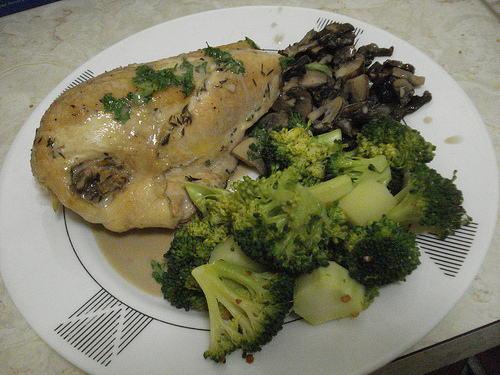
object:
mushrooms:
[267, 21, 437, 146]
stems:
[294, 263, 366, 323]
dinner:
[31, 17, 469, 361]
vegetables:
[281, 120, 332, 173]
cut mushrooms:
[320, 23, 355, 53]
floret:
[345, 219, 419, 283]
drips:
[444, 133, 462, 148]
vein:
[37, 4, 76, 50]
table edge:
[381, 324, 497, 375]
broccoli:
[229, 175, 351, 277]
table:
[1, 0, 498, 372]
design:
[52, 288, 152, 366]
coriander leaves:
[181, 64, 195, 95]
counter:
[1, 1, 499, 374]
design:
[54, 69, 95, 101]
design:
[317, 16, 366, 48]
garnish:
[100, 47, 246, 125]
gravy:
[96, 223, 177, 287]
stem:
[193, 258, 247, 320]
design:
[413, 214, 479, 278]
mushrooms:
[290, 84, 315, 120]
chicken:
[31, 35, 284, 250]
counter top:
[428, 14, 475, 59]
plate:
[0, 6, 500, 375]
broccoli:
[165, 124, 461, 362]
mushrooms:
[305, 95, 344, 126]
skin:
[52, 103, 89, 157]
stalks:
[314, 178, 349, 199]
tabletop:
[0, 0, 498, 373]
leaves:
[163, 64, 200, 93]